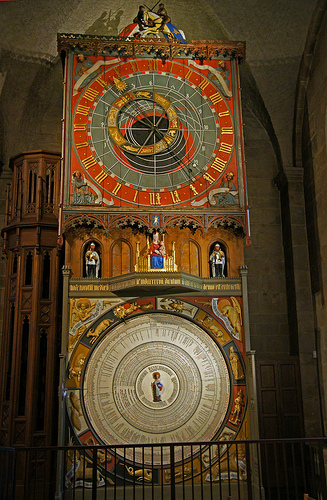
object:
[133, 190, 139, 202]
number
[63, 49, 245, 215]
clock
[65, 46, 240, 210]
clock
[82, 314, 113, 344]
zodiac sign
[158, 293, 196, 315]
zodiac sign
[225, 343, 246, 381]
zodiac sign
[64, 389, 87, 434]
zodiac sign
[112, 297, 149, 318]
zodiac sign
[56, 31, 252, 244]
circle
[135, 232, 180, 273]
throne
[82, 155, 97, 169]
number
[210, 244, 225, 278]
statue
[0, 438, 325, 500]
fence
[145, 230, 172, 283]
woman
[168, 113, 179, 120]
wall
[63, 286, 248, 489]
clock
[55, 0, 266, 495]
tower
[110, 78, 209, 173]
hands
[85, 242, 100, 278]
figurine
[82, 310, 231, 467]
silver portion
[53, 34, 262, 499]
clock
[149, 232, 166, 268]
figurine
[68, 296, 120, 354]
images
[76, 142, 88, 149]
number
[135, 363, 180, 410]
circle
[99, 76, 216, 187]
arrows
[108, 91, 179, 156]
ring